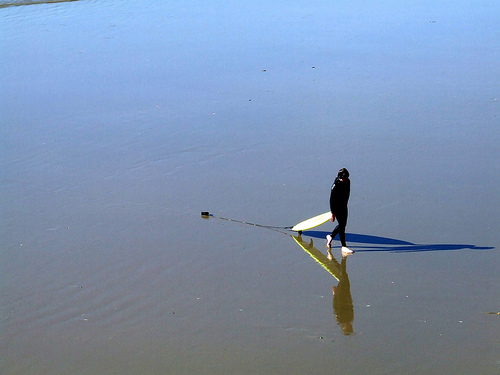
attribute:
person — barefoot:
[328, 166, 356, 252]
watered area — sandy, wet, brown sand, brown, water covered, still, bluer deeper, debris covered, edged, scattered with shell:
[3, 1, 498, 373]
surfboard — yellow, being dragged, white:
[294, 209, 335, 234]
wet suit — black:
[328, 178, 352, 247]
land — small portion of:
[1, 1, 77, 10]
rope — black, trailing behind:
[210, 213, 292, 236]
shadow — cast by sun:
[305, 226, 408, 250]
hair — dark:
[337, 167, 351, 183]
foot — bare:
[326, 235, 335, 249]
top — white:
[292, 213, 335, 229]